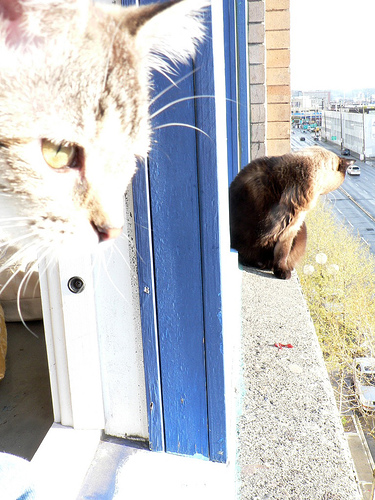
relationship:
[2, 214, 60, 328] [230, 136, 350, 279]
whiskers in cat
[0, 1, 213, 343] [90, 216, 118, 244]
cat has nose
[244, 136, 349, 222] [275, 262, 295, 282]
cat has paw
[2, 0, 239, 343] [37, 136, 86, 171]
eye of cat